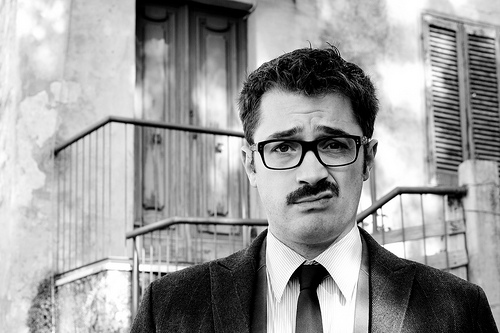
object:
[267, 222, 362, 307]
collar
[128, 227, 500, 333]
crown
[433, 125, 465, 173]
ground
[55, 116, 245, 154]
railings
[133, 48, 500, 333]
he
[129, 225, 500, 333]
coat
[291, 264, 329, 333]
tie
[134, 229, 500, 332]
suit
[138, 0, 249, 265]
door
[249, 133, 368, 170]
black glasses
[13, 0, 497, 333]
building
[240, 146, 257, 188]
ear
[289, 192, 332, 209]
mouth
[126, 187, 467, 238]
railing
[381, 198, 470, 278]
stairs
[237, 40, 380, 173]
hair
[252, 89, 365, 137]
forehead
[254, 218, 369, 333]
shirt.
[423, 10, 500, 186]
shutters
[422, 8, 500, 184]
window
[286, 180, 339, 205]
man`s moustache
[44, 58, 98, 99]
part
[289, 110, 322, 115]
line